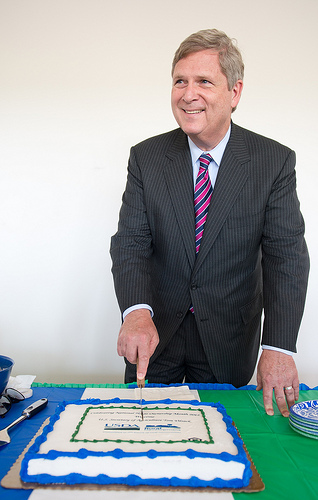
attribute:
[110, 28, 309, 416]
man — preparing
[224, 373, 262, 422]
tablecloth — blue, green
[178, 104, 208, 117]
smile — nice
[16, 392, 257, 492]
cake — rectangular, uncut, blue, white, green, uneaten